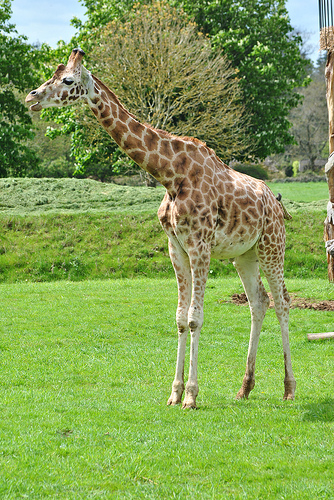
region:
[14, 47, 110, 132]
head of the giraffe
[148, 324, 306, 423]
legs of the giraffe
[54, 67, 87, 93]
eye of the giraffe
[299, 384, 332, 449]
shadow on the ground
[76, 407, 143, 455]
green grass on ground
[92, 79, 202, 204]
neck of the giraffe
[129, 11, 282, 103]
trees behind the giraffe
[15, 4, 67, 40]
sky above the land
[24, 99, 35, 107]
Mouth of giraffe open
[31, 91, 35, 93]
The nostril of the giraffe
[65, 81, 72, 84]
The giraffe's eye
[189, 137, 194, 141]
Mane on the lower neck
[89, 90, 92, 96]
White color on the neck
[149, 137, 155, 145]
Brown spot on the body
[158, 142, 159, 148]
A white stripe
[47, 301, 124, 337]
Grass on the ground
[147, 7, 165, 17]
Flowers on a tree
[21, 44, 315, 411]
a giraffe standing on grass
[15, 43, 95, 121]
the head of a giraffe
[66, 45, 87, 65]
the horns of a giraffe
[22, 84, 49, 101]
the nose of a giraffe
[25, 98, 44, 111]
the mouth of a giraffe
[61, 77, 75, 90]
the eye of a giraffe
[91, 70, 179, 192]
the neck of a giraffe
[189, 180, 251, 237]
the stops of a giraffe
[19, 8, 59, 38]
white clouds in blue sky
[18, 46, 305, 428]
brown and tan spotted giraffe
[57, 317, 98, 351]
short green and yellow grass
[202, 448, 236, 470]
short green and yellow grass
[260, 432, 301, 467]
short green and yellow grass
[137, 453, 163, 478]
short green and yellow grass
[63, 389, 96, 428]
short green and yellow grass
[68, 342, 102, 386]
short green and yellow grass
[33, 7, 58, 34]
white clouds n blue sky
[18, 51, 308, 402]
tan and brown giraffe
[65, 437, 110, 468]
short green and yellow grass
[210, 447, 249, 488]
short green and yellow grass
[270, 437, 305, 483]
short green and yellow grass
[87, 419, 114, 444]
short green and yellow grass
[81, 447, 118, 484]
short green and yellow grass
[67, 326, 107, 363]
short green and yellow grass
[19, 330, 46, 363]
short green and yellow grass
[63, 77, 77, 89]
Eye of a giraffe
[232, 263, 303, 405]
Legs of a giraffe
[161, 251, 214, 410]
Legs of a giraffe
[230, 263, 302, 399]
Legs of a giraffe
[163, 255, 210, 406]
Legs of a giraffe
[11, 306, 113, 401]
Large patch of grass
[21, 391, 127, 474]
Large patch of grass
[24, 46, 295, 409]
tall tan and brown giraffe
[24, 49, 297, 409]
giraffe standing on grass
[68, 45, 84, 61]
pair of brown and black giraffe antlers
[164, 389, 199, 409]
two front giraffe hooves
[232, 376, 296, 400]
two brown giraffe hooves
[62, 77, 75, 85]
droopy black giraffe eye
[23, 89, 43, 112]
open giraffe mouth and black nostril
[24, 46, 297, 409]
giraffe standing in a sunny field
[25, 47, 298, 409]
tall giraffe on green grass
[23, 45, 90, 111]
giraffe head with open mouth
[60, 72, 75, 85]
eye of the giraffe